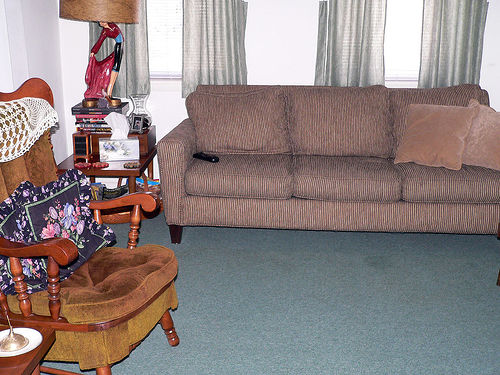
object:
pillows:
[393, 104, 476, 171]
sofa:
[156, 84, 499, 244]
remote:
[193, 151, 220, 163]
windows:
[242, 0, 318, 86]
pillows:
[460, 98, 500, 172]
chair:
[1, 77, 179, 374]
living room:
[0, 0, 500, 375]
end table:
[56, 146, 157, 194]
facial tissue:
[103, 111, 130, 140]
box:
[98, 136, 140, 162]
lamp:
[59, 0, 139, 115]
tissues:
[99, 112, 141, 171]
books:
[83, 124, 111, 129]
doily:
[0, 97, 59, 163]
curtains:
[314, 0, 386, 87]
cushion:
[6, 244, 179, 325]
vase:
[127, 94, 152, 130]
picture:
[130, 115, 145, 135]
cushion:
[294, 156, 403, 203]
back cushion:
[185, 84, 293, 155]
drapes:
[180, 0, 246, 99]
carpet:
[347, 325, 499, 372]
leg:
[169, 224, 183, 245]